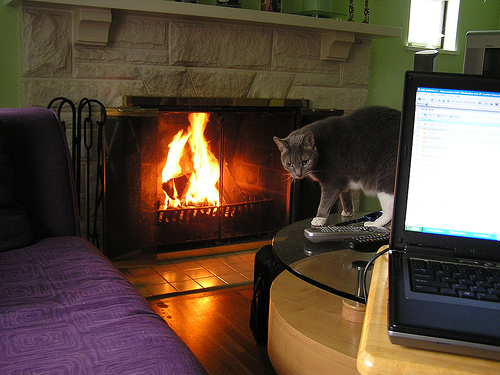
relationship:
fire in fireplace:
[163, 127, 228, 196] [94, 64, 284, 275]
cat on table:
[273, 104, 399, 226] [269, 210, 389, 302]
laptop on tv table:
[387, 68, 498, 361] [356, 240, 498, 373]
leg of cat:
[357, 190, 396, 229] [273, 104, 399, 226]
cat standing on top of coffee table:
[273, 104, 399, 226] [272, 208, 390, 295]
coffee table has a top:
[255, 203, 376, 373] [265, 203, 387, 293]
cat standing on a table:
[267, 101, 389, 227] [257, 208, 378, 372]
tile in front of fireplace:
[120, 260, 246, 286] [118, 91, 307, 231]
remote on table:
[352, 236, 400, 246] [273, 203, 362, 367]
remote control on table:
[303, 224, 382, 238] [273, 203, 362, 367]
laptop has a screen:
[387, 68, 498, 361] [414, 88, 498, 244]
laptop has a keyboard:
[387, 68, 498, 361] [411, 257, 497, 301]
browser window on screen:
[416, 93, 487, 220] [402, 72, 499, 247]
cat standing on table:
[273, 104, 399, 226] [269, 210, 389, 302]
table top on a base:
[272, 215, 392, 302] [268, 245, 376, 371]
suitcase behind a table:
[253, 242, 288, 354] [268, 213, 378, 373]